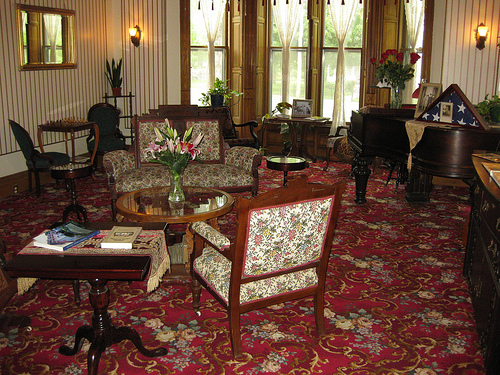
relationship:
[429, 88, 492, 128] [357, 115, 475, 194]
flag on piano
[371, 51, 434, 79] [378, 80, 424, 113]
roses in vase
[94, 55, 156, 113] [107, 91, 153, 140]
plant on shelf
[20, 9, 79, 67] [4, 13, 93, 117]
mirror on wall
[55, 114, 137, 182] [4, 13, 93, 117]
sidebar against wall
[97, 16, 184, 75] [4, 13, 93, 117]
light on wall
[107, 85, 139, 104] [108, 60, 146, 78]
pot has greenery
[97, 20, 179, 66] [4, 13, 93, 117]
lights on wall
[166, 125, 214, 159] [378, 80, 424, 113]
flowers in vase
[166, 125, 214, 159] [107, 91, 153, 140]
flowers on shelf